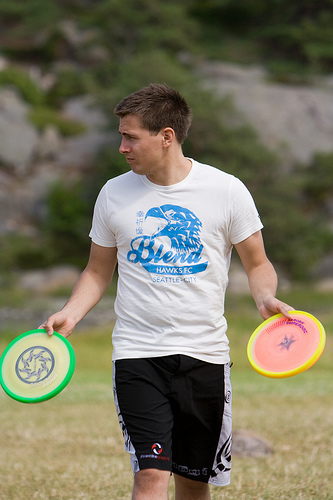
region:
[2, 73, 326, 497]
man walking with two frisbees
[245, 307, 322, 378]
yellow frisbee in man's left hand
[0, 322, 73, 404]
green frisbee in man's right hand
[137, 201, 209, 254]
image of a hawk on man's shirt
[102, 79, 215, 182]
face of a man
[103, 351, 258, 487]
black and white shorts on man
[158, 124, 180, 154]
left ear of a man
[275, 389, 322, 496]
grass in a park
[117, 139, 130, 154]
nose of a man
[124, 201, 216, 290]
image on a man's t-shirt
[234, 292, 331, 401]
a yellow and orange frisbee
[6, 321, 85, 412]
a green and yellow frisbee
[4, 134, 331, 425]
a man holding two frisbees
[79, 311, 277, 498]
black and white shorts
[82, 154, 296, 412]
a blue and white shirt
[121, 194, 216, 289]
a blue hawk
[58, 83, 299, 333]
a man with brown hair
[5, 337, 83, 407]
a strange sun shape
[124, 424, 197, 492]
a red and white logo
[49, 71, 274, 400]
a man wearing a white shirt and black shorts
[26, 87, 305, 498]
Man wearing white shirt and black shorts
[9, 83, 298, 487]
Man holds green and yellow disc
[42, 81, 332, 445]
Man holds pink and yellow disc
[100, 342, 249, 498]
Shorts are black white and red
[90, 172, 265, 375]
Shirt is white and blue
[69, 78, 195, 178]
Man has short brown hair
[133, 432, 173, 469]
Red and white emblem on shorts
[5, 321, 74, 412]
Circular design in middle of green disc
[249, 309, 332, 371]
Odd shaped design on orange disc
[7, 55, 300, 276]
Green foliage behind man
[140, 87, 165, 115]
hair of a man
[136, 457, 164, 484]
part of a knee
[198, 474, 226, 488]
edge of a short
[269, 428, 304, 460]
part of a ground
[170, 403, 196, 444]
part of a short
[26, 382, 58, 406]
edge of a dish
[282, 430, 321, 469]
part of a grass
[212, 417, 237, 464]
edge of a short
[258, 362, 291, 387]
edge of a dish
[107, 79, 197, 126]
Dark brown hair on man's head.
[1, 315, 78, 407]
Frisby in man's left hand.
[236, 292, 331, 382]
Frisby in man's right hand.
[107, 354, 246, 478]
Man is wearing black shorts.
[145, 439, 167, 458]
Red and white symbol on man's shorts.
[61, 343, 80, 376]
Green outline on frisby.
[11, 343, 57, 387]
Blue sun design in middle of frisby.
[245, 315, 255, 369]
Yellow trim on frisby.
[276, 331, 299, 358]
Black design in middle of frisby.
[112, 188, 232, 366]
Man wears white tshirt with blue design.